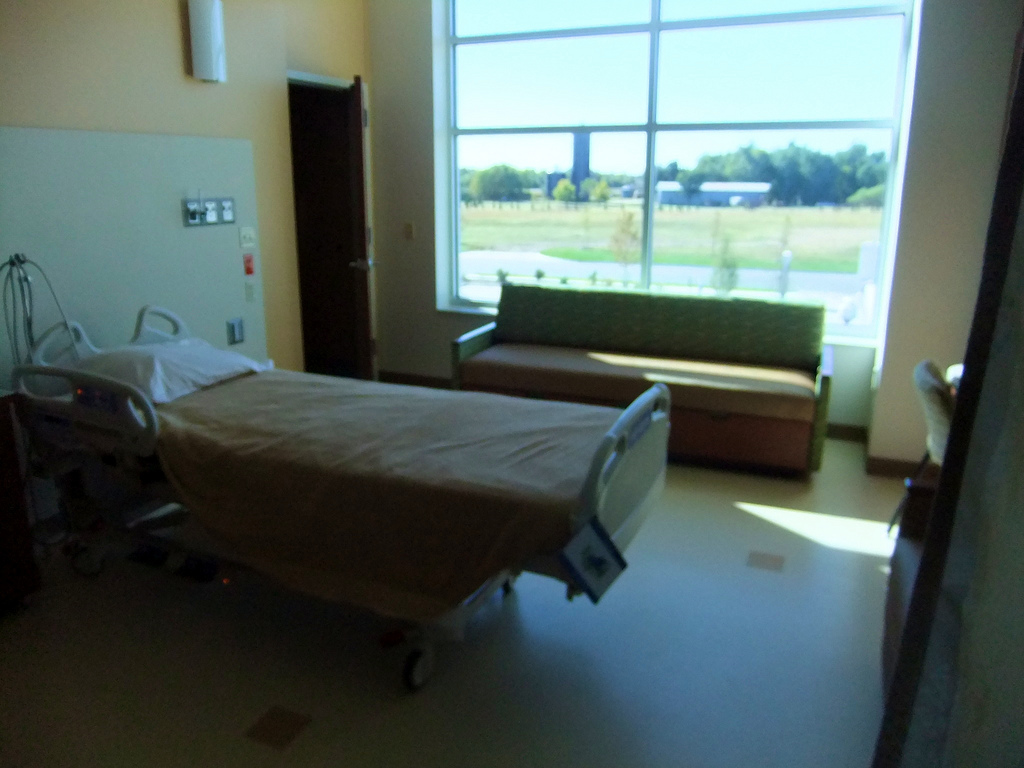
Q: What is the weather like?
A: It is clear.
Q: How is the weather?
A: It is clear.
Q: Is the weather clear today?
A: Yes, it is clear.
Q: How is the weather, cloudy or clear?
A: It is clear.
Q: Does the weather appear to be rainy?
A: No, it is clear.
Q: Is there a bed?
A: Yes, there is a bed.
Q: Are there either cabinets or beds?
A: Yes, there is a bed.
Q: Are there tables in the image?
A: No, there are no tables.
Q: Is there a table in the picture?
A: No, there are no tables.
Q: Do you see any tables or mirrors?
A: No, there are no tables or mirrors.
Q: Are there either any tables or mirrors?
A: No, there are no tables or mirrors.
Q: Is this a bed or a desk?
A: This is a bed.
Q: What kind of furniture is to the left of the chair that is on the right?
A: The piece of furniture is a bed.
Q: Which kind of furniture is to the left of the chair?
A: The piece of furniture is a bed.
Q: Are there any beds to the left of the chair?
A: Yes, there is a bed to the left of the chair.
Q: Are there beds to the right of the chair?
A: No, the bed is to the left of the chair.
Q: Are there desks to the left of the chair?
A: No, there is a bed to the left of the chair.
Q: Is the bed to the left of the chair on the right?
A: Yes, the bed is to the left of the chair.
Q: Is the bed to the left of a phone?
A: No, the bed is to the left of the chair.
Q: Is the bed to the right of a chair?
A: No, the bed is to the left of a chair.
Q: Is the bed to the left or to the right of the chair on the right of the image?
A: The bed is to the left of the chair.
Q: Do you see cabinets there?
A: No, there are no cabinets.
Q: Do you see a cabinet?
A: No, there are no cabinets.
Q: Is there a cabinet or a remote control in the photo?
A: No, there are no cabinets or remote controls.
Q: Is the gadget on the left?
A: Yes, the gadget is on the left of the image.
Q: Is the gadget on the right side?
A: No, the gadget is on the left of the image.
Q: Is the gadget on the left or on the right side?
A: The gadget is on the left of the image.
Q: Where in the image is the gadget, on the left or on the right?
A: The gadget is on the left of the image.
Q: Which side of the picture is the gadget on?
A: The gadget is on the left of the image.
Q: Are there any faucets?
A: No, there are no faucets.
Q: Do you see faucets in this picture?
A: No, there are no faucets.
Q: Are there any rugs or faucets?
A: No, there are no faucets or rugs.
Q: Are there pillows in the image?
A: Yes, there is a pillow.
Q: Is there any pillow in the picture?
A: Yes, there is a pillow.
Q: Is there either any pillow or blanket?
A: Yes, there is a pillow.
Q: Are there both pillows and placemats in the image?
A: No, there is a pillow but no placemats.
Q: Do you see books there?
A: No, there are no books.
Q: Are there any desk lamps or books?
A: No, there are no books or desk lamps.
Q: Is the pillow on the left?
A: Yes, the pillow is on the left of the image.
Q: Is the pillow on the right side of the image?
A: No, the pillow is on the left of the image.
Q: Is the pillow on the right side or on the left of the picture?
A: The pillow is on the left of the image.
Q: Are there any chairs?
A: Yes, there is a chair.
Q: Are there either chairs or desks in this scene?
A: Yes, there is a chair.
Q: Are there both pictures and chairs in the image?
A: No, there is a chair but no pictures.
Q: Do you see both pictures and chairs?
A: No, there is a chair but no pictures.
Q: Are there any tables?
A: No, there are no tables.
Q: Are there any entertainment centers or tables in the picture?
A: No, there are no tables or entertainment centers.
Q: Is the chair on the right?
A: Yes, the chair is on the right of the image.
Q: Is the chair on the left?
A: No, the chair is on the right of the image.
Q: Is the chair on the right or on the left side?
A: The chair is on the right of the image.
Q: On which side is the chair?
A: The chair is on the right of the image.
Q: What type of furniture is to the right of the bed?
A: The piece of furniture is a chair.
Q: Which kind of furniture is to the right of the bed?
A: The piece of furniture is a chair.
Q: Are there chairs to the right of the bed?
A: Yes, there is a chair to the right of the bed.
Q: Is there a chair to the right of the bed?
A: Yes, there is a chair to the right of the bed.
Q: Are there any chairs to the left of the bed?
A: No, the chair is to the right of the bed.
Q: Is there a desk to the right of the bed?
A: No, there is a chair to the right of the bed.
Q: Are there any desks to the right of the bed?
A: No, there is a chair to the right of the bed.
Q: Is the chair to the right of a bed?
A: Yes, the chair is to the right of a bed.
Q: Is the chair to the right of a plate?
A: No, the chair is to the right of a bed.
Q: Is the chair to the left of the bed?
A: No, the chair is to the right of the bed.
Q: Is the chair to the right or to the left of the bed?
A: The chair is to the right of the bed.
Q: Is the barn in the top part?
A: Yes, the barn is in the top of the image.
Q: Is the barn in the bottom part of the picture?
A: No, the barn is in the top of the image.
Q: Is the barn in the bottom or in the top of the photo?
A: The barn is in the top of the image.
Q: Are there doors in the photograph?
A: Yes, there is a door.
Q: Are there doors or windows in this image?
A: Yes, there is a door.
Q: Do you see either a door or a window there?
A: Yes, there is a door.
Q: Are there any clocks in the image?
A: No, there are no clocks.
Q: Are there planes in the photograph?
A: No, there are no planes.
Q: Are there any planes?
A: No, there are no planes.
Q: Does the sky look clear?
A: Yes, the sky is clear.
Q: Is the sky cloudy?
A: No, the sky is clear.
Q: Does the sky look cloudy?
A: No, the sky is clear.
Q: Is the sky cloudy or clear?
A: The sky is clear.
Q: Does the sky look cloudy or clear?
A: The sky is clear.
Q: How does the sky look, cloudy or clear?
A: The sky is clear.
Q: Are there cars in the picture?
A: No, there are no cars.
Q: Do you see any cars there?
A: No, there are no cars.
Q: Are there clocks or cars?
A: No, there are no cars or clocks.